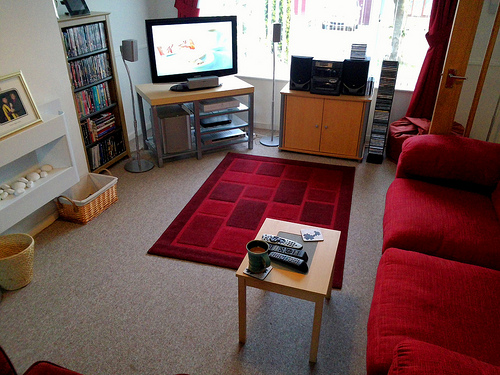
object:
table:
[235, 218, 341, 363]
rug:
[142, 146, 363, 290]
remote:
[261, 233, 303, 250]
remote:
[268, 244, 306, 258]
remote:
[269, 251, 305, 267]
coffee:
[246, 240, 271, 273]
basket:
[54, 173, 118, 225]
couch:
[365, 126, 499, 374]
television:
[145, 16, 237, 93]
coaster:
[243, 265, 274, 280]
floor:
[57, 224, 149, 349]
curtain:
[407, 0, 461, 119]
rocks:
[10, 177, 26, 195]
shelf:
[0, 0, 91, 345]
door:
[428, 0, 500, 144]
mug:
[246, 239, 271, 273]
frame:
[0, 68, 44, 141]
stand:
[133, 74, 254, 168]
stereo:
[289, 55, 371, 97]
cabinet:
[277, 82, 374, 162]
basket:
[0, 232, 34, 290]